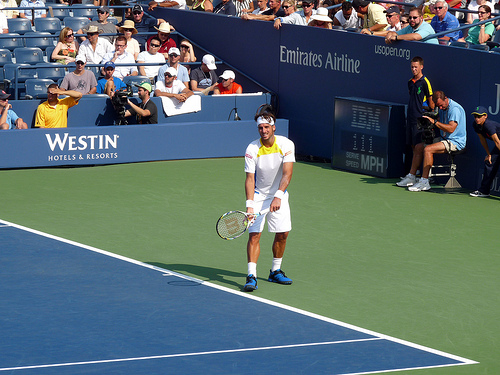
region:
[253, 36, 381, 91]
advertisement for Emirates Airline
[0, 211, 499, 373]
blue tennis court with white lines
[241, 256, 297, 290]
bright blue tennis shoes with white socks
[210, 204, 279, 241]
Wilson tennis racket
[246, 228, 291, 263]
very muscular white man's calves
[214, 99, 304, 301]
tennis player wearing mostly white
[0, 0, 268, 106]
group of spectators and empty seats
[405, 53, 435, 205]
teenage ball boy standing tall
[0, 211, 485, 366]
white baseline on a tennis court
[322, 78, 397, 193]
miles per hour tracker on a tennis court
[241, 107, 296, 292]
Man tennis player preparing to serve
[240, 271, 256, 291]
Blue and black shoe on man tennis player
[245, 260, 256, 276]
White sock on man tennis player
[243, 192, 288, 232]
White shorts on man tennis player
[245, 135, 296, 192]
White shirt on man tennis player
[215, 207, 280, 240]
Tennis racket in hands of man player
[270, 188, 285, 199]
White wristband on man tennis player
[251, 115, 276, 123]
White headband on man tennis player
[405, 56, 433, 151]
Ball person standing at tennis match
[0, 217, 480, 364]
White baseline on tennis court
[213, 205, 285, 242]
A Wilson tennis racket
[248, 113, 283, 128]
A white tennis head band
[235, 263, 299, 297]
Blue and black tennis shoes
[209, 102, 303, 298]
A tennis player holding a racket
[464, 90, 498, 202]
A ball boy for a tennis match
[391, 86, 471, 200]
A man sitting in a chair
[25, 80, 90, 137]
A man covering his eyes from the sun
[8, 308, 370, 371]
A blue tennis playing court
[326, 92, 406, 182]
A sign that reads 111 miles per hour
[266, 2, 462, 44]
Fans watching a tennis match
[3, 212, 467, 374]
blue game area of a tennis court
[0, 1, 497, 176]
stands for spectators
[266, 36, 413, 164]
sponsers of the tennis game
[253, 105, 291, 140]
p;layer wears a sweatband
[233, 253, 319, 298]
blue tennis shoes with white crew socks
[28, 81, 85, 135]
man in yellow shirt shades eyes from sun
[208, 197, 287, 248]
a wilson made tennis racquet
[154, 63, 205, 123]
man leaning against a white towel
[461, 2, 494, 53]
spectator wears mint green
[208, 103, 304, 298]
person on a tennis court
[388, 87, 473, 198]
person on a tennis court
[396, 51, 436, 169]
person on a tennis court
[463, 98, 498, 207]
person on a tennis court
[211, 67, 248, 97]
person sitting in the stands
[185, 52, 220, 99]
person sitting in the stands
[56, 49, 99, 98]
person sitting in the stands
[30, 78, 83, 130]
person sitting in the stands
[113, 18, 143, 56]
person sitting in the stands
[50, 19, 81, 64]
person sitting in the stands